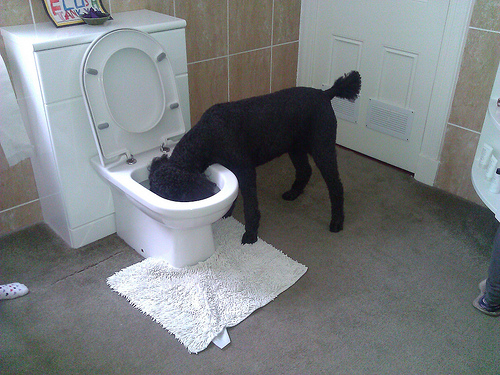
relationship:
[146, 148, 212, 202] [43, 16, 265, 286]
head in toilet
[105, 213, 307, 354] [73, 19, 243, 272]
floor mat around toilet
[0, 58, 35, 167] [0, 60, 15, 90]
paper hanging from roll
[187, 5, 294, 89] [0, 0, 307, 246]
tiles on wall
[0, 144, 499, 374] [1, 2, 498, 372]
floor in bathroom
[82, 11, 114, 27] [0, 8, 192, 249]
bowl on top of tank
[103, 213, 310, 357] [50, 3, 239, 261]
floor mat in front of toilet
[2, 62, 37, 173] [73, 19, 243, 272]
paper next to toilet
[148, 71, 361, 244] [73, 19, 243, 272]
black dog drinking from a toilet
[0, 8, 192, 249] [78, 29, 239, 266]
tank behind a toilet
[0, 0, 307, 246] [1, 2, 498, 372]
wall of bathroom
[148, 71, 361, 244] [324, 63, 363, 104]
black dog has tail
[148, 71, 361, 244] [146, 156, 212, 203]
black dog has head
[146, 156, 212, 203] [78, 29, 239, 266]
head in toilet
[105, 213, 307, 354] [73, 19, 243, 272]
floor mat under toilet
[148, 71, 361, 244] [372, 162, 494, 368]
black dog on floor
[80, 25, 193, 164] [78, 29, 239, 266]
seat on toilet